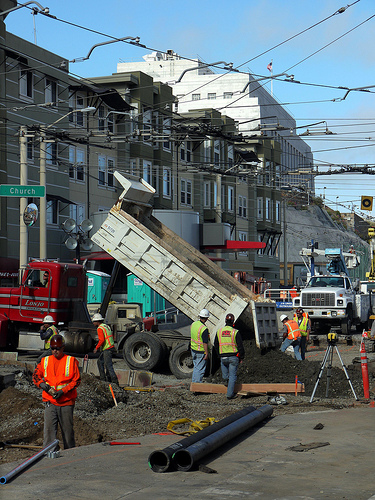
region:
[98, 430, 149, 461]
A red tool laying on the ground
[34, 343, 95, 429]
a man wearing orange safety vest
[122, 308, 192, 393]
a black tire on the truck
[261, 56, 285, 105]
an American flag on the roof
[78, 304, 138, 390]
A man wearing a helment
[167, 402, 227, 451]
yellow straps laying on the ground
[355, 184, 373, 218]
a yellow sign with a black circle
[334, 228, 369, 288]
a man in the bucket of the truck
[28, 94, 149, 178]
power lines hanging from a pole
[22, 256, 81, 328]
a man driving a red truck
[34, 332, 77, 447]
man wearing red hard hat and orange vest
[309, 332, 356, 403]
surveyors tripod with yellow gadget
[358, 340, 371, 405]
orange safety cone leaning to the left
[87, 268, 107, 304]
teal blue port-o-pot for use by construction crew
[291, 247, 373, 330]
white utility truck parked on the street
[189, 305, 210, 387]
construction worker with white hat and yellow vest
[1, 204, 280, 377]
dump truck with a red cab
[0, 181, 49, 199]
sign for church street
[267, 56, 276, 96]
united state flag flying atop a building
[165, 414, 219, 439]
a pile of yellow caution tape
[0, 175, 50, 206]
Green street sign with the name Church on it.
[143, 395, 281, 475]
Two large black sewer pipes sitting on the ground.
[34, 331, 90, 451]
Man wearing an orange reflective vest.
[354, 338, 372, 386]
Orange and white safety cone.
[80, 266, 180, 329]
Two green and white port-a-potties.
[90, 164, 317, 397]
White dump truck dumping dirt on the ground.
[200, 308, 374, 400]
Large pile of dark brown dirt.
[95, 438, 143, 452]
Red handled pipe wrench.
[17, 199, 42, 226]
Round mirror attached to the pole.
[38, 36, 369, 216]
Sky filled with wires and cables.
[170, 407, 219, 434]
yellow straps laying on the ground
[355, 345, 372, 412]
A red pole standing in the ground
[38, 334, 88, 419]
A man wearing safety clothes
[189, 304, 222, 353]
A man wearing a white helment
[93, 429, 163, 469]
a red tool laying on the ground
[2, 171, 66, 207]
A green sign with the name of the street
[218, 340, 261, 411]
A person wearing blue jeans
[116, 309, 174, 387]
A black tire on the truck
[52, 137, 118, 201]
Windows on the building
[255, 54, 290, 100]
An American flag on top of the building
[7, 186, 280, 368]
a dump truck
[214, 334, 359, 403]
a fresh load of dark gravel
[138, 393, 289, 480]
two metal pipes on the ground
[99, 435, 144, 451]
a pipe wrench with a red handle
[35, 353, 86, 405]
an orange vest on a man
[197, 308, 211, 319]
a white safety helmet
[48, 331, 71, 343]
a black safety helmet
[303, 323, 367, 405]
survey equipment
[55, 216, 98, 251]
four lights grouped together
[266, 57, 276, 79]
a flag on top of a building